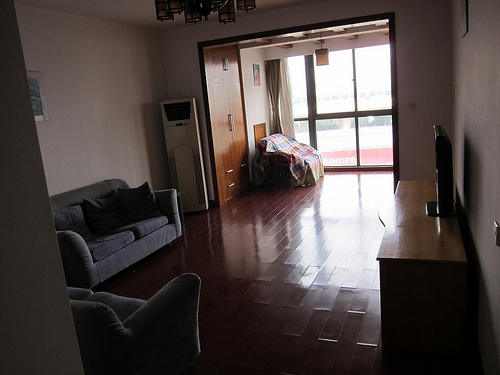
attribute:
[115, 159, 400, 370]
floor — brown wood, buffed, woodlike, dark wood, wooden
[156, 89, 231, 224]
appliance — white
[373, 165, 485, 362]
cabinet — wooden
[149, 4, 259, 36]
light fixture — hanging, black, cylindrical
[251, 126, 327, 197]
chair — blanket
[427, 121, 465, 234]
tv — black, off, flat screen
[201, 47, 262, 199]
closet — wooden, wood, storage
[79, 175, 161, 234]
pillows — dark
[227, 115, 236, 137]
handles — silver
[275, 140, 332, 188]
blanket — plaid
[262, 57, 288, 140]
curtains — privacy, tied back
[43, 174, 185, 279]
couch — set, gray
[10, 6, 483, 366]
office — waiting room